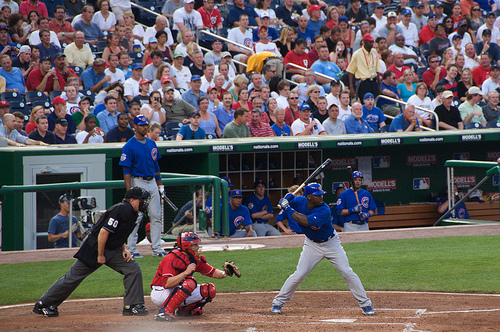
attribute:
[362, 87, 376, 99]
hat — backwards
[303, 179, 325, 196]
helmet — blue 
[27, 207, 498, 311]
grass — Green 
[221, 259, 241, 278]
mitt — leather  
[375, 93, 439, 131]
pole — silver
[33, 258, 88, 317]
leg — stretched back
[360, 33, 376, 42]
hat — red 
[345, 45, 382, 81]
shirt — yellow 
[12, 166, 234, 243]
pole — green , long 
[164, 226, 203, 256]
helmet — red 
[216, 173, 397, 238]
players — Numerous 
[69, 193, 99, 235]
camera — for filming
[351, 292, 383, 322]
shoe — man's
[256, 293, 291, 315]
shoe — man's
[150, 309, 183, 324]
shoe — man's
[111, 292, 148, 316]
shoe — man's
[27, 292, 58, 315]
shoe — man's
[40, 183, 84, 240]
man — filming event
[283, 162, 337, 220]
baseball bat — brown , black 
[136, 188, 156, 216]
face guard — black 